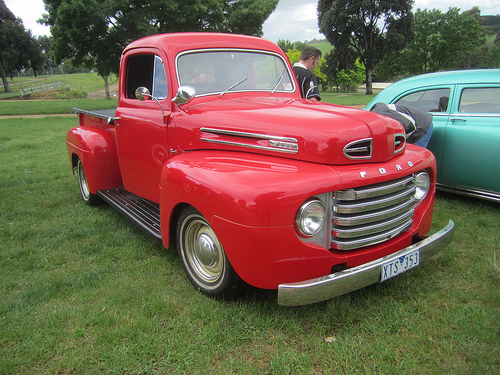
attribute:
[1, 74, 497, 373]
grass — red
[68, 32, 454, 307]
truck — classic, antique, red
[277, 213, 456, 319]
bumper — silver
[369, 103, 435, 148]
person —  bending over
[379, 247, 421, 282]
license plate — white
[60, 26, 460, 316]
pickup — antique, red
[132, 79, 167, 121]
mirror — rearview, chrome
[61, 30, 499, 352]
scene —  outside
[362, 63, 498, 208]
car — green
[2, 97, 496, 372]
field — green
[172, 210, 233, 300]
tire — black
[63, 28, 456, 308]
pickup truck — shiny, cherry red, old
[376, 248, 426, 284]
plate — white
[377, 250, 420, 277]
letters — blue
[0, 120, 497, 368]
field — green, grassy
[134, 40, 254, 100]
windshield — glass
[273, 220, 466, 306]
bumper — chrome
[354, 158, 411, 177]
ford sign — silver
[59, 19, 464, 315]
truck — old fashion, red